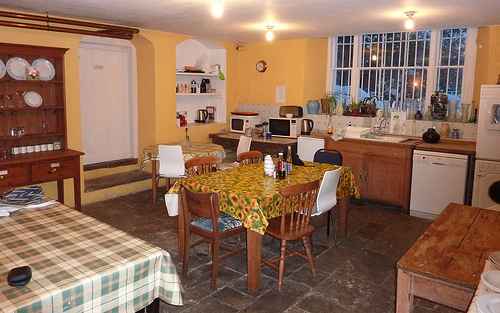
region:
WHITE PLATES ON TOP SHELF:
[7, 61, 29, 73]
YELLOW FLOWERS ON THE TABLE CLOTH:
[228, 197, 240, 202]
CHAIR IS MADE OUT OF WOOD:
[277, 181, 323, 274]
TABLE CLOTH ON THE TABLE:
[236, 196, 268, 243]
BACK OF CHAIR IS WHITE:
[316, 175, 338, 213]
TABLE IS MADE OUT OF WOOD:
[428, 229, 468, 263]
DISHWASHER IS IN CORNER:
[427, 158, 459, 203]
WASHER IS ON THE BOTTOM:
[478, 177, 494, 204]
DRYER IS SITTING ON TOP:
[486, 102, 496, 139]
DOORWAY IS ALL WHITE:
[75, 51, 132, 158]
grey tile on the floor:
[56, 195, 431, 308]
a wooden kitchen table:
[156, 147, 367, 289]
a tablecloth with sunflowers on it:
[171, 156, 362, 229]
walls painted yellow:
[3, 30, 498, 215]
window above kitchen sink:
[322, 27, 474, 127]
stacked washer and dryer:
[471, 77, 497, 207]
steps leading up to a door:
[65, 156, 160, 201]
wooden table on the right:
[396, 200, 497, 310]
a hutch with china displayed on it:
[2, 46, 83, 204]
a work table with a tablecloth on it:
[4, 203, 183, 312]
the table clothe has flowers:
[214, 153, 272, 230]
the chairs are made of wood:
[180, 184, 337, 284]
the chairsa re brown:
[175, 193, 329, 278]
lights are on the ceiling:
[204, 4, 434, 54]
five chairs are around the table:
[182, 146, 353, 271]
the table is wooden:
[408, 192, 496, 302]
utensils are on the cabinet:
[5, 55, 70, 154]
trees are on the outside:
[335, 50, 459, 91]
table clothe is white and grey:
[26, 230, 174, 310]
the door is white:
[87, 51, 159, 160]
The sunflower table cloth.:
[185, 165, 361, 227]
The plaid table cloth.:
[2, 196, 178, 306]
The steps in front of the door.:
[87, 155, 152, 199]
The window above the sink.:
[332, 34, 462, 106]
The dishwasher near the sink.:
[412, 152, 470, 216]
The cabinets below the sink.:
[330, 146, 404, 205]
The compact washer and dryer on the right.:
[472, 88, 498, 210]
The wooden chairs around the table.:
[170, 143, 321, 272]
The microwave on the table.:
[269, 116, 296, 138]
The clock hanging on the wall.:
[253, 59, 267, 72]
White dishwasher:
[405, 144, 470, 222]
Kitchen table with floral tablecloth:
[161, 150, 356, 296]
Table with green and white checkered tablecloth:
[1, 194, 186, 312]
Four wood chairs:
[159, 152, 336, 298]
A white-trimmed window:
[315, 24, 483, 124]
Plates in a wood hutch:
[0, 54, 57, 121]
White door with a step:
[70, 24, 154, 205]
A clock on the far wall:
[250, 57, 267, 74]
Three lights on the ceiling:
[201, 2, 428, 47]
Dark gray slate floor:
[65, 184, 467, 312]